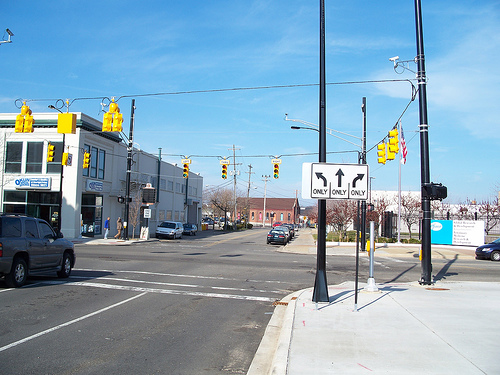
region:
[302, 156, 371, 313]
A traffic sign in the foreground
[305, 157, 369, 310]
Traffic sign is white in color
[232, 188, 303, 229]
A brown building in the background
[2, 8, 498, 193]
Clouds are in the sky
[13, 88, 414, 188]
Traffic lights are yellow in color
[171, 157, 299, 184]
Traffic lights are on the green light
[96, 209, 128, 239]
Two people on the sidewalk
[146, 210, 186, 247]
A white van in the background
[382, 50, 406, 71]
Traffic cam in the background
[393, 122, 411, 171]
An American flag in the background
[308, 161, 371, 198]
black and white direction sign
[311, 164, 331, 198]
turning left sign arrow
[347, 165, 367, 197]
turning right sign arrow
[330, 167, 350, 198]
arrow point straight up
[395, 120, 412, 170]
red white and blue flag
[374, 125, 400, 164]
two yellow signal lights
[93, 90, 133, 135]
signal light hanging on wire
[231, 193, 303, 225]
red brick church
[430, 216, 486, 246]
blue and white sign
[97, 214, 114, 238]
man wearing blue shirt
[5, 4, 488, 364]
A suburban street scene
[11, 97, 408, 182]
these are traffic signal lights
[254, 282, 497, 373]
This is the sidewalk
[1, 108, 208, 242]
A building is along the street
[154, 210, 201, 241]
Cars are parked next to the building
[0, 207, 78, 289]
An SUV is on the street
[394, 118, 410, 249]
An American flag on a pole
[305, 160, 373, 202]
A street sign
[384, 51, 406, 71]
A traffic camera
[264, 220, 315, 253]
Cars are parked along the sidewalk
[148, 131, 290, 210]
the lights are green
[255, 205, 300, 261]
the cars are parked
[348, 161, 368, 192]
the arrow is pointing right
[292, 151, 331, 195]
the arrow is pointing left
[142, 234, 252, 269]
shadow of the traffic lights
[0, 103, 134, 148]
the traffic lights are yellow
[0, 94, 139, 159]
the back of the traffic lights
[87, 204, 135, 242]
two people on the corner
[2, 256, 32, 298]
the tire is black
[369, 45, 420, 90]
a camera on the pole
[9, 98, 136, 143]
back of yellow traffic lights hanging on a wire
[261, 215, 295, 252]
cars parked on the side of the street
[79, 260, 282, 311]
white lines painted on the pavement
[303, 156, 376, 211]
black and white street sign on a pole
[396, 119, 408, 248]
American flag on a pole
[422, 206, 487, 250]
blue and white sign across the street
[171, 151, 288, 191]
traffic lights showing the red light lit up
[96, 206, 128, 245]
people standing on a street corner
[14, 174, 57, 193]
blue and white sign on a building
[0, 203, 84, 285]
vehicle stopped at the intersection